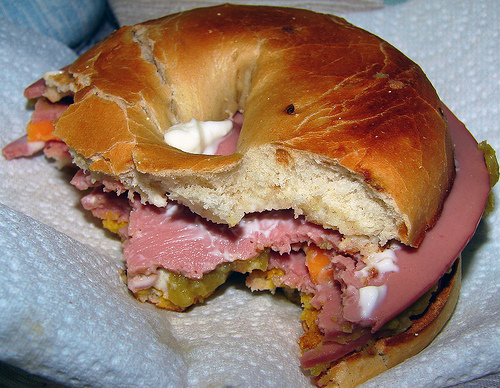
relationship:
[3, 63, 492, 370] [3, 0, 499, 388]
bologna on bagel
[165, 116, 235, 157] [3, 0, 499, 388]
mayonaise on bagel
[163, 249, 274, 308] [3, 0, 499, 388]
pickle on bagel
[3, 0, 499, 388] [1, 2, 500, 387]
bagel on a paper towel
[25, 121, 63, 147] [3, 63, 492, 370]
cheese on top of bologna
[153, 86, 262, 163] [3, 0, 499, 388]
hole in center of bagel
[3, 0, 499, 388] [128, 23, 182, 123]
bagel has a crease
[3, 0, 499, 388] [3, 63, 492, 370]
bagel has bologna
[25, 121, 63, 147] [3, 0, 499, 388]
cheese on bagel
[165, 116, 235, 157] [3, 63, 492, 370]
mayonaise on bologna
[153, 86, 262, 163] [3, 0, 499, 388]
hole in bagel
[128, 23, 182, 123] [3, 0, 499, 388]
crease on bagel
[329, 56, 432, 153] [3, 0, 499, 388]
dark spot on bagel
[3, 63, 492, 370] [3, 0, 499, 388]
bologna hanging out of bagel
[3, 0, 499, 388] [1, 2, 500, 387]
bagel on paper towel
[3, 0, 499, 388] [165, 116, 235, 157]
bagel has mayonaise